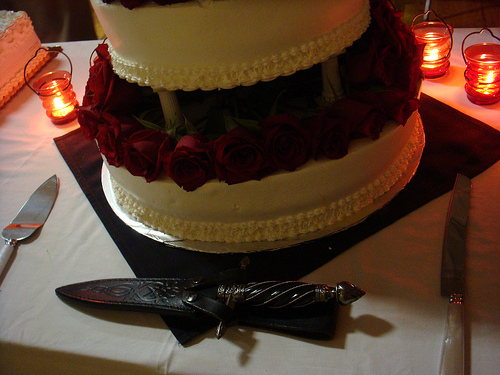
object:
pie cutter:
[435, 173, 477, 372]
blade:
[438, 169, 475, 302]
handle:
[435, 296, 471, 373]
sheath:
[56, 269, 232, 316]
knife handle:
[214, 270, 368, 343]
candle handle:
[19, 44, 74, 95]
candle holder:
[35, 67, 78, 124]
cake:
[0, 8, 46, 110]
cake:
[85, 1, 427, 239]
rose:
[161, 131, 213, 194]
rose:
[208, 123, 266, 185]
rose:
[254, 111, 310, 172]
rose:
[302, 107, 351, 165]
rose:
[328, 95, 383, 140]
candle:
[49, 93, 75, 122]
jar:
[16, 41, 85, 126]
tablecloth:
[2, 23, 495, 370]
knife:
[51, 274, 365, 344]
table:
[0, 9, 500, 375]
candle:
[407, 7, 453, 82]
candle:
[462, 22, 496, 105]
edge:
[0, 7, 61, 116]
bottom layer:
[101, 91, 424, 254]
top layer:
[90, 2, 376, 89]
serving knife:
[0, 173, 63, 293]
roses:
[351, 28, 421, 101]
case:
[51, 77, 500, 345]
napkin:
[49, 36, 500, 349]